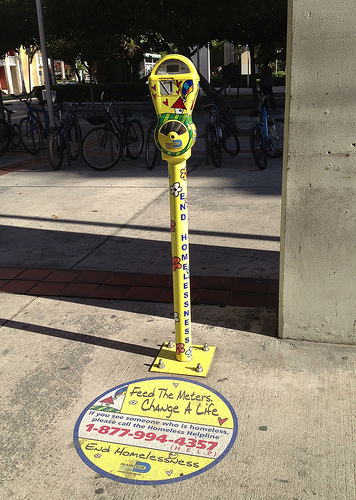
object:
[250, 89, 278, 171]
bicycle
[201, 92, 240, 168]
bicycle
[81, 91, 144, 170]
bicycle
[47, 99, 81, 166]
bicycle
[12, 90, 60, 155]
bicycle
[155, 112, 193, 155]
green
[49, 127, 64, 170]
tire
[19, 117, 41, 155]
tire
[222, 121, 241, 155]
tire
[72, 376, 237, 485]
sign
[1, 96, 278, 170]
row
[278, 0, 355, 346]
wall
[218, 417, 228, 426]
red heart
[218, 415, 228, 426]
right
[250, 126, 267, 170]
tire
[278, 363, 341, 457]
dog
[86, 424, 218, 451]
number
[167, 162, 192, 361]
pole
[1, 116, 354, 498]
side walk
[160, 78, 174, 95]
money slot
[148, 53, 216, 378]
parking meter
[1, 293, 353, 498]
street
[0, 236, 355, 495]
ground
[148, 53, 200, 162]
colored meter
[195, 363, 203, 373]
bolt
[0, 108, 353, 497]
sidewalk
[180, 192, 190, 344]
blue lettering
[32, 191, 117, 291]
shadow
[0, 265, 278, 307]
bricks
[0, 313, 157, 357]
shadow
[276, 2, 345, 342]
pole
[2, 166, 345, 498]
pavement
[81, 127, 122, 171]
tire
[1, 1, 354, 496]
city